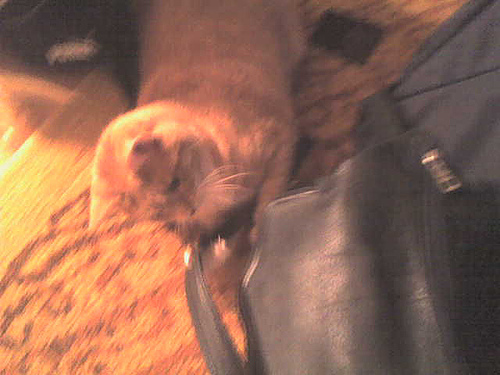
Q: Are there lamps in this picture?
A: No, there are no lamps.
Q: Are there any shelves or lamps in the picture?
A: No, there are no lamps or shelves.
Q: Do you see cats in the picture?
A: Yes, there is a cat.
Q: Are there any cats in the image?
A: Yes, there is a cat.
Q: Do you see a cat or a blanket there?
A: Yes, there is a cat.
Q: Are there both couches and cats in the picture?
A: No, there is a cat but no couches.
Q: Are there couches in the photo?
A: No, there are no couches.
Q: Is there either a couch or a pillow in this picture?
A: No, there are no couches or pillows.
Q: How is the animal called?
A: The animal is a cat.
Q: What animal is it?
A: The animal is a cat.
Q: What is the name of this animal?
A: This is a cat.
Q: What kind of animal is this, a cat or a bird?
A: This is a cat.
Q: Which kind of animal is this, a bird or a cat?
A: This is a cat.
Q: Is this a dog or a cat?
A: This is a cat.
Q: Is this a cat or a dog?
A: This is a cat.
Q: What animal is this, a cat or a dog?
A: This is a cat.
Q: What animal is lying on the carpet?
A: The cat is lying on the carpet.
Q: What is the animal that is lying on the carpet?
A: The animal is a cat.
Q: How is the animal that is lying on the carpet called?
A: The animal is a cat.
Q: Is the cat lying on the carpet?
A: Yes, the cat is lying on the carpet.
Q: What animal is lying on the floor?
A: The cat is lying on the floor.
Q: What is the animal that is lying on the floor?
A: The animal is a cat.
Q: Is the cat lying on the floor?
A: Yes, the cat is lying on the floor.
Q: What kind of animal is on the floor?
A: The animal is a cat.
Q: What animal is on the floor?
A: The cat is on the floor.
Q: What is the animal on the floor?
A: The animal is a cat.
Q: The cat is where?
A: The cat is on the floor.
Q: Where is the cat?
A: The cat is on the floor.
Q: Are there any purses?
A: Yes, there is a purse.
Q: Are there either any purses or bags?
A: Yes, there is a purse.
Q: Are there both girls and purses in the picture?
A: No, there is a purse but no girls.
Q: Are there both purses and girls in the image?
A: No, there is a purse but no girls.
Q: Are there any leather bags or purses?
A: Yes, there is a leather purse.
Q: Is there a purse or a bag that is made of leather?
A: Yes, the purse is made of leather.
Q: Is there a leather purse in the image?
A: Yes, there is a purse that is made of leather.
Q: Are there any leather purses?
A: Yes, there is a purse that is made of leather.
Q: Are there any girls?
A: No, there are no girls.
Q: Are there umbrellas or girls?
A: No, there are no girls or umbrellas.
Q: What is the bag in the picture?
A: The bag is a purse.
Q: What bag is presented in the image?
A: The bag is a purse.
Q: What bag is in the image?
A: The bag is a purse.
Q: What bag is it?
A: The bag is a purse.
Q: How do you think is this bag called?
A: This is a purse.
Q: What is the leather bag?
A: The bag is a purse.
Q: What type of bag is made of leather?
A: The bag is a purse.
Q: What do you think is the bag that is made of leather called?
A: The bag is a purse.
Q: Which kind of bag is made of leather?
A: The bag is a purse.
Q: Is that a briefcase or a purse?
A: That is a purse.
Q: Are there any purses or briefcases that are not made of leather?
A: No, there is a purse but it is made of leather.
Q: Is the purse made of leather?
A: Yes, the purse is made of leather.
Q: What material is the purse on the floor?
A: The purse is made of leather.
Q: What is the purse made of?
A: The purse is made of leather.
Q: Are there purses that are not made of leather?
A: No, there is a purse but it is made of leather.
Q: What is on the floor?
A: The purse is on the floor.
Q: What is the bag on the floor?
A: The bag is a purse.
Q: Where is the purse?
A: The purse is on the floor.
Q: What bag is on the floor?
A: The bag is a purse.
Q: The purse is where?
A: The purse is on the floor.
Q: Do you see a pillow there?
A: No, there are no pillows.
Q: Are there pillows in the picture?
A: No, there are no pillows.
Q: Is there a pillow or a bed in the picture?
A: No, there are no pillows or beds.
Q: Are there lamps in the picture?
A: No, there are no lamps.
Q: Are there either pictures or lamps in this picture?
A: No, there are no lamps or pictures.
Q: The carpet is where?
A: The carpet is on the floor.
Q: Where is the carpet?
A: The carpet is on the floor.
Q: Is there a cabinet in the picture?
A: No, there are no cabinets.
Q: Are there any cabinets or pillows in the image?
A: No, there are no cabinets or pillows.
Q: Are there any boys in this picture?
A: No, there are no boys.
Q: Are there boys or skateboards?
A: No, there are no boys or skateboards.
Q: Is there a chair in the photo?
A: No, there are no chairs.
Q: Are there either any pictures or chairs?
A: No, there are no chairs or pictures.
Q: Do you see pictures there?
A: No, there are no pictures.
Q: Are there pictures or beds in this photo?
A: No, there are no pictures or beds.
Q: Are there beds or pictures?
A: No, there are no pictures or beds.